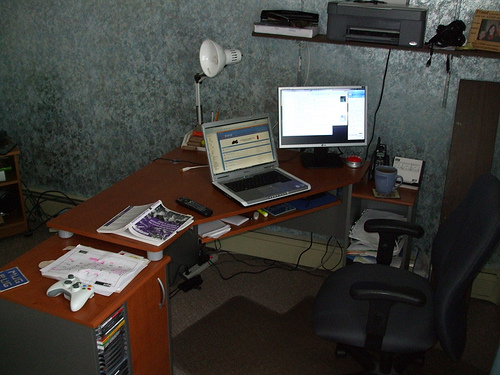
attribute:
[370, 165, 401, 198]
cup — cupis